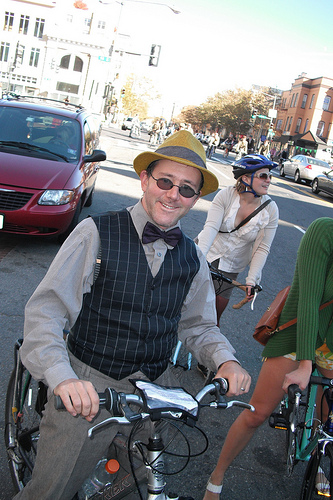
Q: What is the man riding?
A: A grey mountain bike.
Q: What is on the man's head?
A: A yellow hat with grey band.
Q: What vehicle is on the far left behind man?
A: A maroon car.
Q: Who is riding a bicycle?
A: The man wearing a hat.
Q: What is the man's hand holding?
A: Handlebars on a bicycle.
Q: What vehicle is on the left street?
A: A red car.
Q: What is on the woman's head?
A: A helmet.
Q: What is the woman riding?
A: A bike.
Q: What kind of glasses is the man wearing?
A: Sunglasses.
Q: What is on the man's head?
A: A hat.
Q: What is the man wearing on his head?
A: A hat.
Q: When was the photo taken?
A: Day time.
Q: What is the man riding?
A: A bicycle.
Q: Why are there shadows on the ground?
A: From the building.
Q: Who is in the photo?
A: Cyclists on their bicycles.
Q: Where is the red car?
A: Behind the cyclists.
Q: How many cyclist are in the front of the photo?
A: 3.